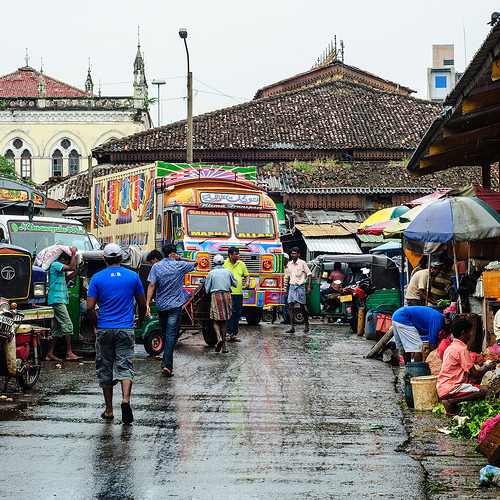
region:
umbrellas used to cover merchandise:
[345, 170, 497, 256]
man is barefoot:
[21, 331, 91, 376]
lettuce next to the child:
[456, 385, 496, 425]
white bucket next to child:
[407, 365, 452, 430]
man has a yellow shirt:
[226, 250, 256, 300]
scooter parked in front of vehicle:
[1, 315, 61, 402]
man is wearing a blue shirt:
[82, 260, 125, 326]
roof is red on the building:
[9, 68, 79, 103]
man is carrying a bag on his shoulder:
[15, 230, 90, 311]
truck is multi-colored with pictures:
[98, 161, 337, 350]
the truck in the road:
[65, 153, 281, 320]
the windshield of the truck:
[181, 202, 285, 238]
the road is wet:
[228, 383, 343, 476]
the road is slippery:
[181, 370, 318, 474]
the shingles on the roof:
[226, 87, 430, 139]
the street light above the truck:
[141, 12, 213, 111]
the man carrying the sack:
[26, 242, 92, 348]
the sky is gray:
[246, 20, 314, 64]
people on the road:
[42, 240, 329, 344]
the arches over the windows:
[0, 136, 75, 152]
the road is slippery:
[265, 375, 370, 467]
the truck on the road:
[85, 167, 290, 302]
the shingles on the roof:
[235, 110, 375, 141]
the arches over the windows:
[0, 140, 85, 180]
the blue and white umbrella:
[394, 191, 490, 253]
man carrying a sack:
[29, 242, 95, 346]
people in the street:
[66, 222, 381, 325]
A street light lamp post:
[173, 26, 203, 163]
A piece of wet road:
[193, 342, 345, 499]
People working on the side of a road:
[382, 291, 497, 412]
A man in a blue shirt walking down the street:
[83, 243, 150, 426]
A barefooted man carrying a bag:
[31, 232, 89, 370]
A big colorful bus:
[89, 161, 310, 320]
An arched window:
[43, 129, 92, 185]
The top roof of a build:
[0, 49, 72, 91]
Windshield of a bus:
[231, 208, 278, 240]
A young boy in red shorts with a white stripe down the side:
[436, 315, 489, 417]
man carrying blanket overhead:
[26, 229, 91, 372]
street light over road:
[152, 20, 238, 82]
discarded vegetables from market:
[409, 368, 499, 447]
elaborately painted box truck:
[79, 158, 303, 313]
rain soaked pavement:
[65, 349, 353, 499]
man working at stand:
[345, 282, 465, 379]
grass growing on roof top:
[269, 139, 379, 186]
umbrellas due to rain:
[336, 183, 493, 248]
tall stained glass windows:
[10, 132, 86, 189]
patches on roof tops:
[297, 208, 372, 246]